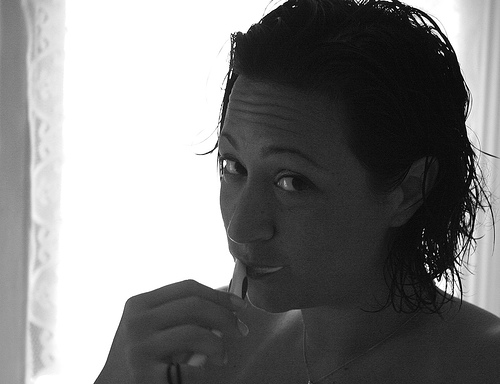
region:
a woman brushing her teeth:
[94, 1, 499, 381]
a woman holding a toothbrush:
[94, 0, 499, 381]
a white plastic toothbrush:
[187, 260, 244, 366]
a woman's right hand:
[92, 278, 247, 382]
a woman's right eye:
[218, 157, 247, 176]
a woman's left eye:
[272, 168, 323, 195]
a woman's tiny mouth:
[233, 258, 289, 275]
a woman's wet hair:
[199, 1, 494, 317]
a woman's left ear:
[388, 153, 436, 228]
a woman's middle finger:
[143, 295, 252, 337]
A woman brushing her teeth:
[60, 15, 485, 381]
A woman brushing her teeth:
[75, 11, 475, 377]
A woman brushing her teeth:
[90, 15, 475, 380]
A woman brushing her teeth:
[85, 8, 478, 363]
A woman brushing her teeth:
[82, 17, 472, 368]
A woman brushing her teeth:
[76, 10, 476, 365]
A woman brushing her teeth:
[80, 5, 478, 372]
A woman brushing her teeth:
[82, 7, 464, 373]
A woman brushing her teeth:
[85, 6, 460, 366]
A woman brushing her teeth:
[78, 8, 470, 373]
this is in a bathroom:
[16, 21, 450, 328]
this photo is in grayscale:
[42, 44, 457, 318]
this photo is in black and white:
[50, 37, 464, 317]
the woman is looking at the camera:
[225, 137, 400, 296]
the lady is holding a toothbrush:
[182, 249, 328, 366]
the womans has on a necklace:
[279, 332, 350, 382]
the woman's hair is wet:
[254, 31, 493, 250]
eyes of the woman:
[211, 153, 311, 200]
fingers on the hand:
[132, 293, 234, 348]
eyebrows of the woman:
[210, 122, 327, 174]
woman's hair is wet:
[412, 130, 471, 273]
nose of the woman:
[227, 206, 277, 246]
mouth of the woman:
[222, 255, 292, 288]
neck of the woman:
[278, 286, 452, 331]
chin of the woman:
[242, 281, 297, 317]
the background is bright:
[82, 53, 170, 160]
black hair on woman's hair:
[245, 1, 475, 86]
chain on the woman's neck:
[296, 322, 397, 379]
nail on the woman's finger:
[231, 313, 250, 336]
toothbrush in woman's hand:
[187, 254, 247, 370]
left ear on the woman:
[389, 152, 440, 238]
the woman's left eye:
[276, 160, 314, 207]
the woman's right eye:
[215, 150, 247, 189]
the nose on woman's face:
[224, 182, 260, 251]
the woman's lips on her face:
[226, 249, 292, 280]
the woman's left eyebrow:
[264, 137, 327, 175]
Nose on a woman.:
[226, 166, 275, 244]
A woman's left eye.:
[275, 171, 310, 193]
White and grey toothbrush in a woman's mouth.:
[187, 253, 248, 368]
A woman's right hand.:
[102, 279, 251, 383]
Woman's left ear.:
[388, 155, 439, 226]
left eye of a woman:
[271, 164, 311, 196]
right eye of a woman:
[218, 156, 245, 180]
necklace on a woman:
[292, 316, 392, 382]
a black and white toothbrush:
[198, 261, 256, 366]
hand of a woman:
[82, 274, 249, 382]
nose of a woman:
[218, 203, 272, 246]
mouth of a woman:
[229, 249, 294, 300]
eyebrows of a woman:
[216, 132, 316, 175]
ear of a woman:
[388, 156, 433, 232]